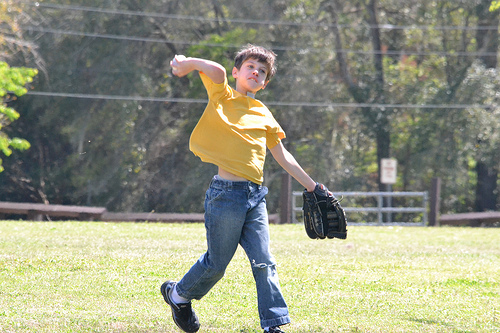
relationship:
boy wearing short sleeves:
[165, 43, 349, 332] [186, 69, 287, 187]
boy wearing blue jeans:
[157, 45, 349, 332] [176, 174, 292, 327]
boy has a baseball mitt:
[157, 45, 349, 332] [299, 186, 351, 245]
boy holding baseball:
[157, 45, 349, 332] [171, 51, 188, 67]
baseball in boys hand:
[171, 51, 188, 67] [166, 52, 192, 81]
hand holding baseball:
[166, 52, 192, 81] [171, 51, 188, 67]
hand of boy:
[166, 52, 192, 81] [157, 45, 349, 332]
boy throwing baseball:
[157, 45, 349, 332] [171, 51, 188, 67]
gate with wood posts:
[291, 186, 434, 230] [277, 159, 448, 229]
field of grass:
[0, 216, 499, 331] [2, 218, 498, 331]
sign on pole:
[381, 158, 400, 185] [384, 182, 392, 225]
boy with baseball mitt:
[157, 45, 349, 332] [299, 186, 351, 245]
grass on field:
[2, 218, 498, 331] [0, 216, 499, 331]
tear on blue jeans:
[253, 258, 277, 274] [176, 174, 292, 327]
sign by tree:
[381, 158, 400, 185] [327, 4, 393, 225]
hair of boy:
[232, 44, 280, 84] [157, 45, 349, 332]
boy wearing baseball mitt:
[157, 45, 349, 332] [299, 186, 351, 245]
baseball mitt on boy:
[299, 186, 351, 245] [157, 45, 349, 332]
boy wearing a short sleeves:
[157, 45, 349, 332] [186, 69, 287, 187]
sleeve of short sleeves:
[200, 70, 228, 94] [186, 69, 287, 187]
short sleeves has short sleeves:
[186, 69, 287, 187] [189, 69, 288, 141]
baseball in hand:
[171, 51, 188, 67] [166, 52, 192, 81]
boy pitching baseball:
[157, 45, 349, 332] [171, 51, 188, 67]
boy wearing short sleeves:
[157, 45, 349, 332] [186, 69, 287, 187]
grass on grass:
[2, 218, 498, 331] [2, 218, 498, 331]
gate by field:
[291, 186, 434, 230] [0, 216, 499, 331]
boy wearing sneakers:
[157, 45, 349, 332] [160, 278, 287, 332]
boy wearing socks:
[157, 45, 349, 332] [173, 284, 192, 304]